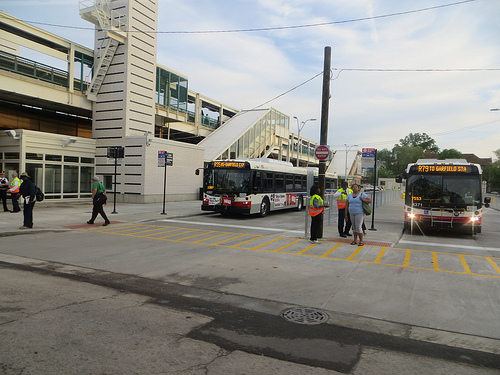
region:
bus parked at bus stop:
[390, 141, 497, 258]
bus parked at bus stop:
[189, 141, 327, 247]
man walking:
[80, 165, 130, 239]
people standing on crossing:
[296, 171, 378, 255]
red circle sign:
[305, 123, 332, 172]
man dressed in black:
[11, 157, 53, 242]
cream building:
[6, 5, 384, 263]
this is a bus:
[387, 123, 494, 254]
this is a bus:
[181, 138, 308, 248]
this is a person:
[340, 172, 377, 260]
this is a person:
[320, 172, 358, 237]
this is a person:
[294, 166, 325, 244]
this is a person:
[72, 161, 124, 241]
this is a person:
[12, 163, 53, 230]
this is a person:
[4, 153, 36, 227]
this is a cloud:
[197, 23, 275, 94]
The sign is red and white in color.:
[310, 143, 332, 160]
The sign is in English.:
[313, 143, 334, 161]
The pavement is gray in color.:
[30, 320, 150, 370]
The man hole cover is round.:
[283, 299, 330, 331]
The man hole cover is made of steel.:
[277, 300, 331, 329]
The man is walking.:
[85, 175, 112, 232]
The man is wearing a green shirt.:
[86, 175, 110, 230]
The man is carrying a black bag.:
[87, 174, 113, 225]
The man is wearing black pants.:
[84, 174, 109, 226]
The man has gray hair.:
[90, 171, 100, 183]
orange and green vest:
[298, 179, 328, 246]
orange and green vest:
[303, 173, 330, 248]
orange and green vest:
[300, 173, 334, 248]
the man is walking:
[74, 163, 119, 245]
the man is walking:
[77, 160, 111, 222]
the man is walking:
[70, 163, 120, 225]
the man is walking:
[69, 160, 114, 243]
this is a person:
[12, 171, 49, 239]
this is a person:
[77, 165, 135, 247]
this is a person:
[340, 182, 382, 249]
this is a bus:
[364, 113, 482, 263]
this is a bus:
[187, 133, 311, 235]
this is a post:
[290, 36, 348, 236]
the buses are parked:
[186, 133, 491, 271]